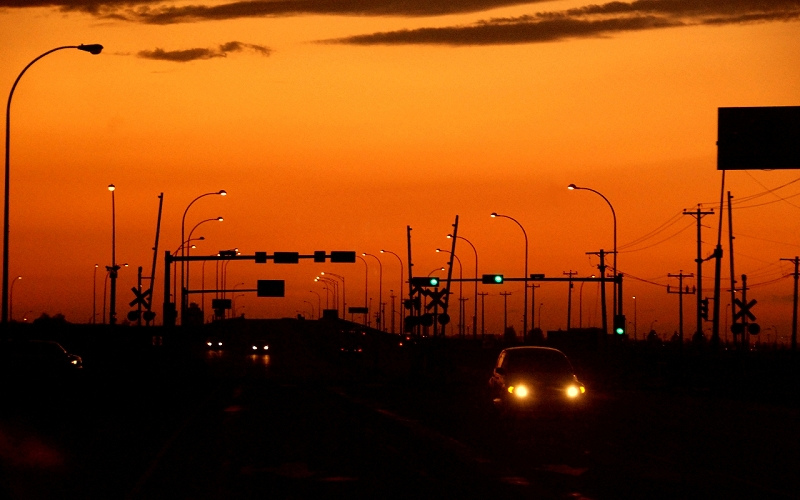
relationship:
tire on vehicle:
[506, 397, 524, 422] [477, 348, 590, 422]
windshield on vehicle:
[510, 348, 576, 374] [482, 330, 594, 420]